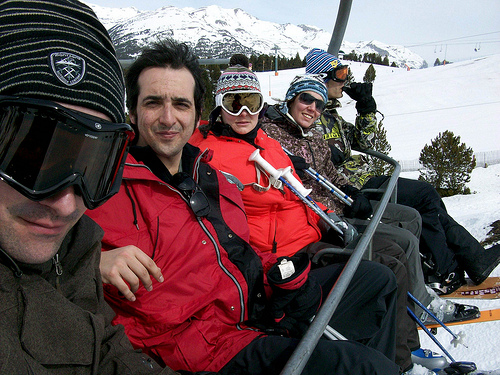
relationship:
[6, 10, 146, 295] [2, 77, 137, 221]
head with goggle